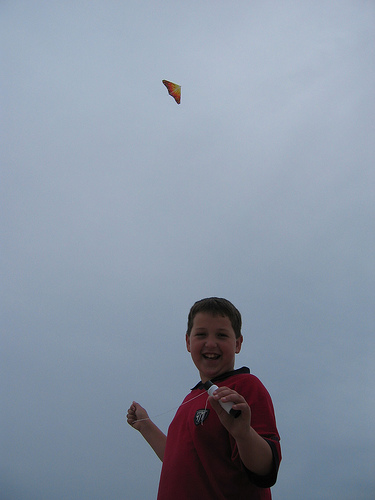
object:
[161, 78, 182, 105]
kite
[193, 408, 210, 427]
logo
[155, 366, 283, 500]
shirt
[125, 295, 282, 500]
boy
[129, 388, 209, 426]
thread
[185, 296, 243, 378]
head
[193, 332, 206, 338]
eyes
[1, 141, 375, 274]
sky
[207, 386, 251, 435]
hand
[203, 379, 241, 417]
spool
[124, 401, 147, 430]
hand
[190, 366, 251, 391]
collar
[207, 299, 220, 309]
hair